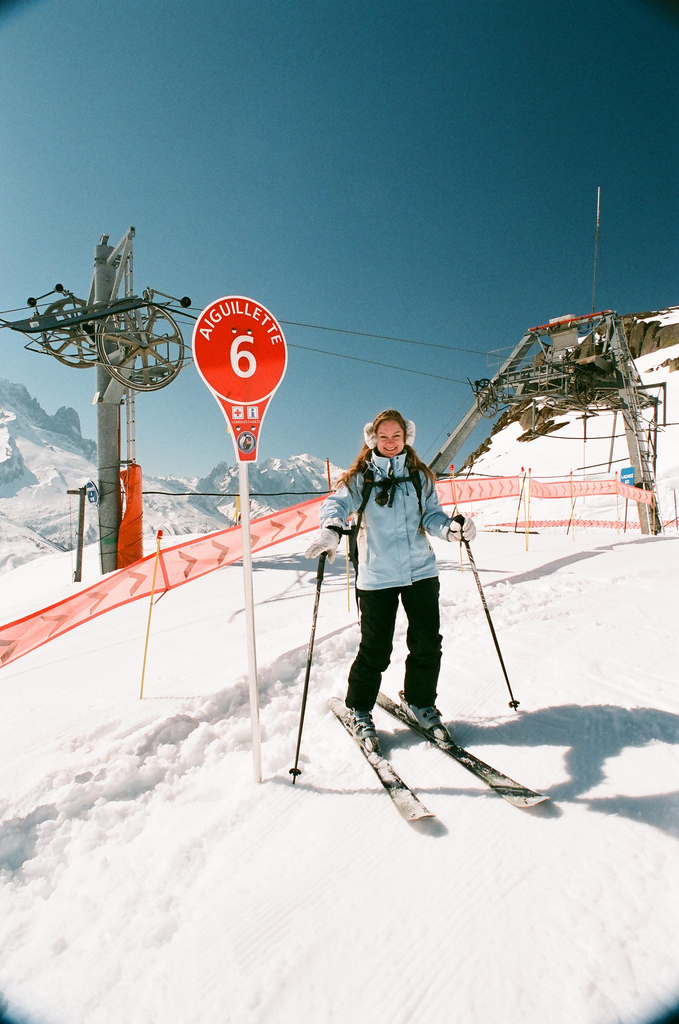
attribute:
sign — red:
[151, 269, 328, 525]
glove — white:
[297, 519, 345, 570]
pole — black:
[262, 506, 356, 805]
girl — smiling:
[328, 386, 443, 620]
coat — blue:
[304, 451, 465, 598]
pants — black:
[343, 574, 441, 714]